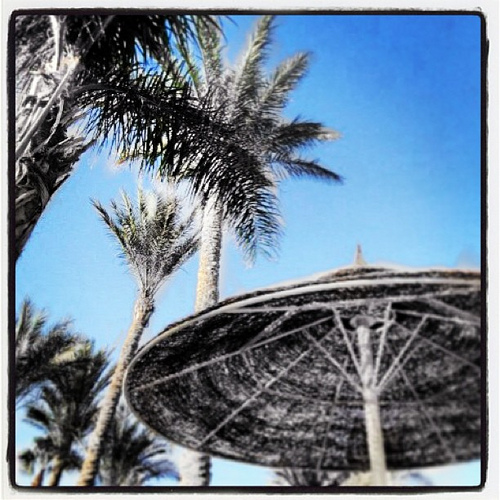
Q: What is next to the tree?
A: Umbrella.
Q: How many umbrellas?
A: 1.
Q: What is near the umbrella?
A: The tree.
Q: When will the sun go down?
A: Soon.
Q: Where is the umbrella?
A: Next to the tree.